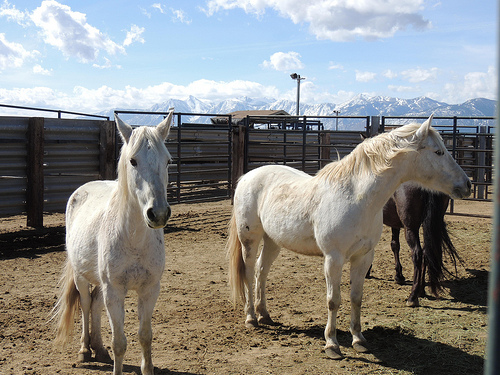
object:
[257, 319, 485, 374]
shadow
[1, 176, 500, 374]
ground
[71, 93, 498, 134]
mountains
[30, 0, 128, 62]
cloud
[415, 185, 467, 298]
tail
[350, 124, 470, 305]
horse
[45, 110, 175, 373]
horse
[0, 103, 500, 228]
fence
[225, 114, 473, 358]
white horses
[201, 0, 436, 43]
cloud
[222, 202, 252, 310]
tail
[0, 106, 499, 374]
corral